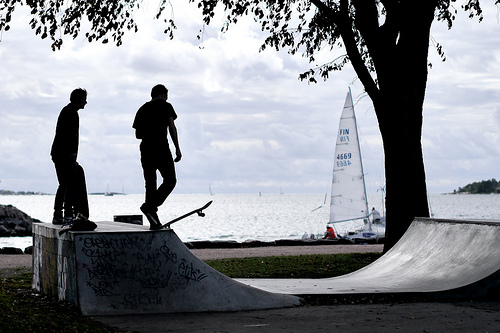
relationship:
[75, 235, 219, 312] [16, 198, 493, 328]
graffiti on ramp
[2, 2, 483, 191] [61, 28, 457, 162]
sky full of clouds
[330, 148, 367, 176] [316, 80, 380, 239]
numbers on sail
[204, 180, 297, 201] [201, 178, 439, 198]
boats on horizon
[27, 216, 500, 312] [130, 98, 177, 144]
halfpipe wearing shirt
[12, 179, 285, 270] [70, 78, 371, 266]
sailboat in water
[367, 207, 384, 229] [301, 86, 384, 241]
person on boat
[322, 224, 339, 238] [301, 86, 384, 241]
person on boat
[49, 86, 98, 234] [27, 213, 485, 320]
guy standing on top of ramp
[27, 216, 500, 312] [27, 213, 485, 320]
halfpipe standing on top of ramp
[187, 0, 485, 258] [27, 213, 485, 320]
tree standing next to ramp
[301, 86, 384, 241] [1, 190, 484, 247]
boat sailing in water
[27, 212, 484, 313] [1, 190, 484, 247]
halfpipe standing next to water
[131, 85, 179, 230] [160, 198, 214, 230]
guy preparing to ride skateboard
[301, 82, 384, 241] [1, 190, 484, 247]
boat sailing on water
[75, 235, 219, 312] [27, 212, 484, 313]
graffiti spray painted on halfpipe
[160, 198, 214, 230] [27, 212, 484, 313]
skateboard balancing on halfpipe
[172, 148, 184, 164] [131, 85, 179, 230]
left hand belonging to guy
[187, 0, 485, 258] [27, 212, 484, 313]
tree standing next to halfpipe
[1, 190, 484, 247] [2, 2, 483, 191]
water flowing underneath sky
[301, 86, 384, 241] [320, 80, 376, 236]
boat has sail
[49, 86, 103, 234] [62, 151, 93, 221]
guy holding skateboard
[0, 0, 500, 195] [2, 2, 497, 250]
cloud in sky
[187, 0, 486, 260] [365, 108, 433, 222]
tree has trunk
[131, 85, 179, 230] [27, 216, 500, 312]
guy standing atop of halfpipe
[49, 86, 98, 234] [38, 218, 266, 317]
guy standing atop of ramp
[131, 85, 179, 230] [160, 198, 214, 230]
guy leaning on skateboard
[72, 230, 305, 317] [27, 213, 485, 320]
side belonging to ramp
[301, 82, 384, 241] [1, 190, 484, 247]
boat sailing in water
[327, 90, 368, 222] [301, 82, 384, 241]
sail hanging on boat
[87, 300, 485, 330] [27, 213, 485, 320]
ground built next to ramp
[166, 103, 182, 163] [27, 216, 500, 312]
arm belonging to halfpipe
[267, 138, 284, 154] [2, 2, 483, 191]
cloud hanging in sky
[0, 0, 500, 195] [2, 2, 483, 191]
cloud hanging in sky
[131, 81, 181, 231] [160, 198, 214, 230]
guy leaning on skateboard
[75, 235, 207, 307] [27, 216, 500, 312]
graffiti painted on halfpipe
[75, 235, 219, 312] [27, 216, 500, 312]
graffiti painted on halfpipe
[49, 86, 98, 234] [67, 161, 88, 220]
guy holding skateboard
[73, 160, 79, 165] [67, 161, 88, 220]
hand holding skateboard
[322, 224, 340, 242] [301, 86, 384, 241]
person sitting in boat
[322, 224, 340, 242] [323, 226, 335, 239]
person wearing orange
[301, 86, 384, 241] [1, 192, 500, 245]
boat sailing in water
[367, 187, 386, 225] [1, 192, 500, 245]
sailboat sailing in water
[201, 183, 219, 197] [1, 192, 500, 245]
sailboat sailing in water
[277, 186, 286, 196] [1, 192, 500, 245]
sailboat sailing in water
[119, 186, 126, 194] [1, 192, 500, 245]
sailboat sailing in water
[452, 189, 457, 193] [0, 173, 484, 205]
tree standing in distance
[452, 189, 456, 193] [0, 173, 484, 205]
tree standing in distance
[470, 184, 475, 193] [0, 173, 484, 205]
tree standing in distance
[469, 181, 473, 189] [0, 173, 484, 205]
tree standing in distance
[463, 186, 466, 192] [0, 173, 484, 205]
tree standing in distance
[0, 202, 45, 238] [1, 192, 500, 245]
pile jutting out of water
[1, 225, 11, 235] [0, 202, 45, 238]
rock lying in pile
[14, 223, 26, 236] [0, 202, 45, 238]
rock lying in pile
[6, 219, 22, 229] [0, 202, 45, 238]
rock lying in pile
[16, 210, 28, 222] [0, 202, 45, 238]
rock lying in pile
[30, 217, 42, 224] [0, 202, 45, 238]
rock lying in pile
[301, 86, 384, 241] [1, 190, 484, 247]
boat sailing at edge of water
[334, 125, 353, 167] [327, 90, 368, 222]
writing printed on sail